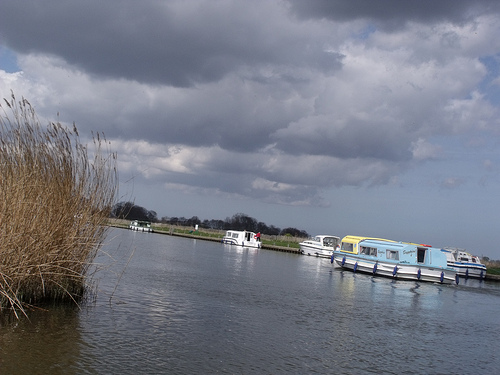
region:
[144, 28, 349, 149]
clouds in the sky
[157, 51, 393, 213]
many white clouds in sky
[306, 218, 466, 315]
boat in the water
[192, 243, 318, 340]
water next to boats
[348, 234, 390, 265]
window on the boat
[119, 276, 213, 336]
light hitting the water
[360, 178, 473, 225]
sky above the land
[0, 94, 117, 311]
Tall tan water rushes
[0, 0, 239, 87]
Dark gray cloud in the sky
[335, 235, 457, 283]
Yellow and blue boat in the water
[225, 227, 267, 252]
White boat near the shore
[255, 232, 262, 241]
Person on boat in red jacket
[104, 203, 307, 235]
Trees growing in the distance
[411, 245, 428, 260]
Doorway in the back of a boat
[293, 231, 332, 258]
White motorboat near the shore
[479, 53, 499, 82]
Blue sky peeking through clouds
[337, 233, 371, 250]
Yellow roof on front of boat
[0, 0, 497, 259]
sky is gray and cloudy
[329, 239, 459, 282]
blue and white boat on the water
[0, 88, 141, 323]
brown plant in the water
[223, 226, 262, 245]
people on a white boat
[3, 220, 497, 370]
white boat on the water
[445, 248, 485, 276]
boat is white and blue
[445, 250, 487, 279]
blue and white boat on the water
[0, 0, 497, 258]
stormy sky above the water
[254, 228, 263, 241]
person wearing a red shirt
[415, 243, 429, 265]
door on the boat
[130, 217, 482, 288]
boats on the water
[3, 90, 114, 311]
reeds growing along the water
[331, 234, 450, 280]
light blue and yellow boat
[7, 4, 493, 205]
gray clouds in the sky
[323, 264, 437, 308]
reflection of boat on the water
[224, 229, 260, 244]
small white boat in the water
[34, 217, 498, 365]
brown water in the waterway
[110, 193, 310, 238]
trees in the far distance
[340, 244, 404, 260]
windows on the boat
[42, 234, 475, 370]
ripples in the water's surface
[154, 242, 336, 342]
the water is calm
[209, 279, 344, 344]
the water is calm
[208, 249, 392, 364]
the water is calm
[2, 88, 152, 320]
a bushel of cat tails by the water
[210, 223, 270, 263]
a small white boat in the water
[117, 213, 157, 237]
a small speed boat parked by a shore